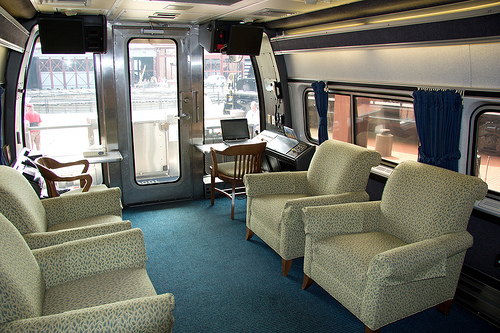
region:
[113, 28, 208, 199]
Silver door in the room.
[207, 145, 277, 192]
Wooden chair in the room.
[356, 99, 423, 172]
Windows looking out of the room.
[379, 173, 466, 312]
A chair with a white and blue pattern.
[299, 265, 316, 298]
Wooden leg of the chair.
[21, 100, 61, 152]
Person standing outside facing the other direction.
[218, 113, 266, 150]
Laptop on a desk.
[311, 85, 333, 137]
Curtains hanging over windows.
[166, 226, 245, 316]
Carpet that is blue.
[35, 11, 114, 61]
TV that is hanging from the ceiling.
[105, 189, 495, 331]
blue carpet on floor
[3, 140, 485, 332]
four speckled chairs with arm rests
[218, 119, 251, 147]
laptop open on desk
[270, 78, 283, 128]
telephone on wall above desk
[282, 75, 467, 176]
blue curtains hanging on rod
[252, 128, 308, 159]
consol near chair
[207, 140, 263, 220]
brown barrel chair in front of laptop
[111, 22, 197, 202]
door with full length window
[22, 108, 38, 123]
person in red shirt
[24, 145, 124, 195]
box on desk next to barrel chair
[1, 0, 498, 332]
remodeled bus as living room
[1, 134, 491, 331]
4 matching blue spotted yellowy chintizish chairs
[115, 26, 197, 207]
bus door as front door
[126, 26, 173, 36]
pneumatic tube thing opens & shuts bus/front door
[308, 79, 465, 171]
blue house curtains on bus/room window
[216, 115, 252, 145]
a little flatscreen monitor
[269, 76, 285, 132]
old landline wall telephone on bus wall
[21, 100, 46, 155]
man wearing red shirt, red hat, black belt, khaki shorts in middle distance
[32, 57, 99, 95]
fancy red accordeon fence, middle distance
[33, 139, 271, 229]
two ordinary brown wood chairs with white pillows as bus/room furniture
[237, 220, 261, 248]
brown leg of a chair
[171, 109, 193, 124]
handle on a door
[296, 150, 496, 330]
chair on the floor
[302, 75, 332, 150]
blue curtains on a window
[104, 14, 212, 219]
door on a train car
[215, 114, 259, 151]
laptop computer on a desk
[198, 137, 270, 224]
brown chair near a desk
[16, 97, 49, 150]
person with a red shirt standing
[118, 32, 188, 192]
window on a door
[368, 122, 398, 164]
trash can outside a window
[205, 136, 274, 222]
A BROWN WOODEN CHAIR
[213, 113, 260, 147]
A LAPTOP ON A DESK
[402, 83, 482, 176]
BLUE CURTAINS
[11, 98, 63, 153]
A MAN IN THE DISTANCE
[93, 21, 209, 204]
A METAL AND GLASS DOOR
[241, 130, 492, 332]
TWO CHAIRS SIDE BY SIDE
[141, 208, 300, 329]
BLUE CARPETING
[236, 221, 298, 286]
WOODEN CHAIR LEGS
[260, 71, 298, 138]
A BLACK PHONE ON A WALL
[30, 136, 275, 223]
TWO WOODEN CHAIRS